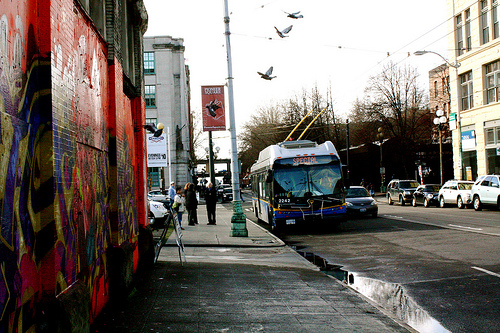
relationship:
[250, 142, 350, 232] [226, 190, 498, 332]
bus on road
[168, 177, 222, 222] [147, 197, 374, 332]
people walking down sidewalk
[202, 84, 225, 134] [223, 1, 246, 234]
red sign attached to pole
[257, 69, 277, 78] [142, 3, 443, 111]
bird in sky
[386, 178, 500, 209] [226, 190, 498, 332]
cars parked along road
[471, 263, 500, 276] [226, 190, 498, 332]
white line on road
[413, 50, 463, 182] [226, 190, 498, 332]
light post next to road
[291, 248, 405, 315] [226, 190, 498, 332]
water along road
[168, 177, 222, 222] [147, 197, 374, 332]
people standing on sidewalk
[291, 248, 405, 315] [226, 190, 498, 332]
puddle of water on road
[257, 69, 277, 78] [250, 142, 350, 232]
bird flying over bus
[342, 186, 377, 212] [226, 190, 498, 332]
car on road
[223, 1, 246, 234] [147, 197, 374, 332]
pole next to sidewalk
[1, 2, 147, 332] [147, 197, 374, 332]
wall next to sidewalk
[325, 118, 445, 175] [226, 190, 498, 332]
tree next to road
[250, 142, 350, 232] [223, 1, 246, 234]
bus next to pole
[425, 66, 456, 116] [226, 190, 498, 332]
building next to road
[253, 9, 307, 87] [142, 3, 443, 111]
birds flying in sky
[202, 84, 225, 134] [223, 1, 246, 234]
sign attached to pole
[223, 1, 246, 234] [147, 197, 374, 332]
pole anchored to sidewalk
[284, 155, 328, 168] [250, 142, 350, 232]
electronic sign on bus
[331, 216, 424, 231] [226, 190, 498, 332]
shadow on road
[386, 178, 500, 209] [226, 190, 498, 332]
cars parked on street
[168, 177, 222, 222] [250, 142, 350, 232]
people waiting for bus